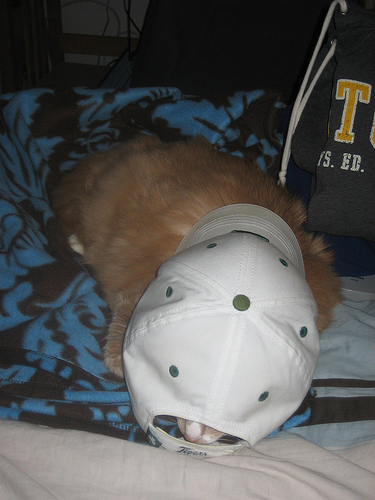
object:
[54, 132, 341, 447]
cat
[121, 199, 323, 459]
hat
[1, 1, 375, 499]
bed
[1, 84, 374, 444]
blanket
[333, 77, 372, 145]
letter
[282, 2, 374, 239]
shirt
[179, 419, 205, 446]
nose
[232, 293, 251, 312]
button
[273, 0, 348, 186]
string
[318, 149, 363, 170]
letters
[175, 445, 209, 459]
word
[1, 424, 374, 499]
sheet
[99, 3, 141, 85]
cords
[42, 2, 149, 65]
wall